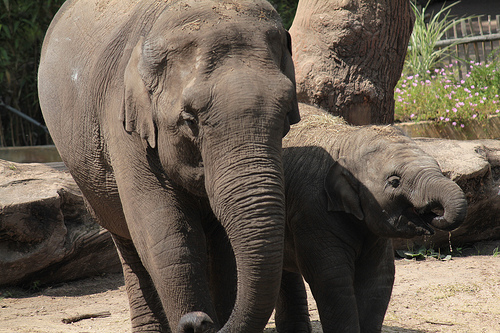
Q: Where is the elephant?
A: In the zoo.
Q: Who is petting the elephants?
A: No one.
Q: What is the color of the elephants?
A: Gray.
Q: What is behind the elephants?
A: Big rocks.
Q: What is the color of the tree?
A: Brown.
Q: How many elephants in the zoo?
A: Two.